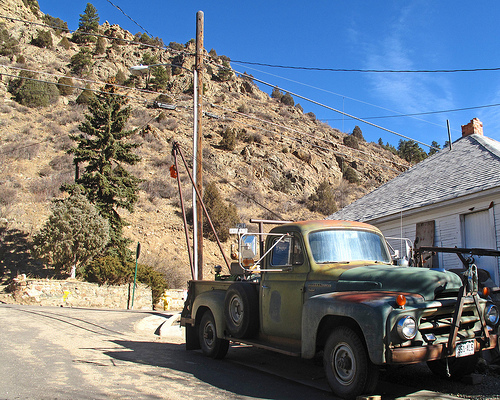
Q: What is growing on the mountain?
A: Trees and bushes.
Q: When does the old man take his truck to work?
A: Late in the day.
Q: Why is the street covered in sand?
A: Because of the arid terrain.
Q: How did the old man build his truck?
A: Using scrap parts from the junkyard.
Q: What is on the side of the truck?
A: A tire.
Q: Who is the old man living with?
A: The old man's wife.